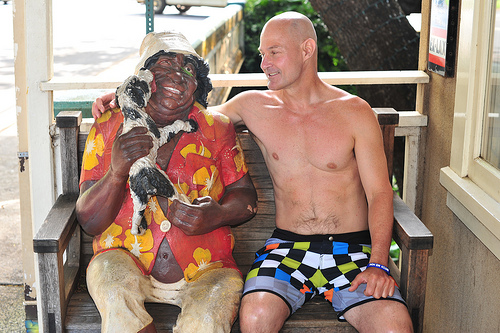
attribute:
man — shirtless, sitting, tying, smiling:
[209, 10, 412, 332]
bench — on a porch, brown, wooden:
[32, 109, 432, 331]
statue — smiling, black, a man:
[73, 30, 258, 332]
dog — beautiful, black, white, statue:
[117, 66, 211, 236]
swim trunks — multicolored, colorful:
[244, 224, 406, 313]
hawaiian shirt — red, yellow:
[81, 105, 246, 279]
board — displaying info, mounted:
[427, 1, 461, 78]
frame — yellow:
[453, 17, 472, 177]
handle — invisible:
[77, 14, 102, 40]